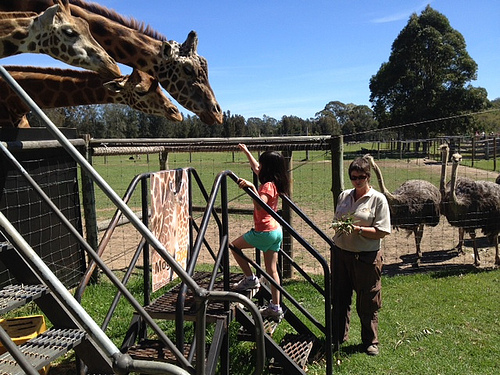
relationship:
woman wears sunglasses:
[323, 151, 402, 352] [349, 171, 371, 183]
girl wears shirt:
[228, 140, 290, 317] [253, 181, 278, 231]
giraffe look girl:
[0, 56, 189, 131] [228, 140, 290, 317]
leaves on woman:
[335, 222, 351, 231] [323, 151, 402, 352]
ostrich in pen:
[363, 155, 440, 269] [11, 119, 498, 369]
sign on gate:
[147, 167, 191, 291] [0, 165, 331, 372]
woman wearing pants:
[323, 151, 402, 352] [324, 243, 381, 345]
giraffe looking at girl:
[4, 6, 127, 81] [235, 138, 291, 319]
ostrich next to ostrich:
[363, 155, 440, 269] [449, 146, 498, 266]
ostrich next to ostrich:
[363, 155, 440, 269] [443, 151, 499, 266]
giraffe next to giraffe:
[118, 36, 210, 113] [4, 6, 127, 81]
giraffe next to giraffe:
[4, 6, 127, 81] [0, 56, 192, 152]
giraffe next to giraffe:
[0, 56, 192, 152] [4, 6, 127, 81]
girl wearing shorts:
[228, 140, 290, 317] [228, 225, 310, 257]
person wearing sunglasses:
[329, 155, 392, 355] [349, 170, 371, 181]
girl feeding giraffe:
[228, 140, 290, 317] [4, 6, 127, 81]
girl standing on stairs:
[228, 140, 290, 317] [138, 260, 326, 373]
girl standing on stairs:
[228, 140, 290, 317] [233, 266, 321, 373]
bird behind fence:
[360, 149, 441, 267] [157, 109, 499, 283]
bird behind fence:
[445, 152, 499, 266] [85, 133, 498, 285]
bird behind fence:
[435, 143, 473, 255] [85, 133, 498, 285]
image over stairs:
[152, 167, 192, 251] [245, 284, 315, 372]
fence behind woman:
[85, 150, 476, 266] [323, 151, 402, 352]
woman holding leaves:
[323, 151, 402, 352] [335, 222, 351, 231]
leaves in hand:
[335, 222, 351, 231] [335, 222, 362, 237]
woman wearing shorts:
[225, 148, 291, 323] [239, 221, 286, 256]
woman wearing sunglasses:
[323, 151, 402, 352] [349, 172, 369, 182]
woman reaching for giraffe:
[225, 148, 291, 323] [4, 6, 127, 81]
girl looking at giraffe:
[228, 140, 290, 317] [4, 6, 127, 81]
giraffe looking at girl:
[0, 56, 189, 131] [228, 140, 290, 317]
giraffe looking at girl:
[4, 6, 127, 81] [228, 140, 290, 317]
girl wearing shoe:
[228, 140, 290, 317] [254, 306, 285, 327]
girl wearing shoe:
[228, 140, 290, 317] [232, 275, 261, 289]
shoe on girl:
[232, 275, 261, 289] [228, 140, 290, 317]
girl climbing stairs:
[228, 140, 290, 317] [138, 260, 326, 373]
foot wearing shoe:
[365, 342, 379, 356] [358, 333, 380, 356]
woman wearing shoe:
[323, 151, 402, 352] [358, 333, 380, 356]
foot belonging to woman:
[365, 342, 379, 356] [323, 151, 402, 352]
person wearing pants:
[329, 155, 392, 355] [320, 239, 387, 347]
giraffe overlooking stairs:
[4, 6, 127, 81] [2, 62, 357, 358]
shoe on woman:
[358, 337, 381, 353] [323, 151, 402, 352]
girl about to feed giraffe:
[228, 140, 290, 317] [120, 4, 222, 130]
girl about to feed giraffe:
[228, 140, 290, 317] [3, 9, 118, 79]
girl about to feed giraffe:
[228, 140, 290, 317] [18, 72, 169, 120]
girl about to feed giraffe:
[228, 140, 290, 317] [4, 6, 127, 81]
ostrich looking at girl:
[363, 155, 440, 269] [228, 140, 290, 317]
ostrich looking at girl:
[445, 155, 498, 270] [228, 140, 290, 317]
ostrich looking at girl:
[433, 140, 452, 219] [228, 140, 290, 317]